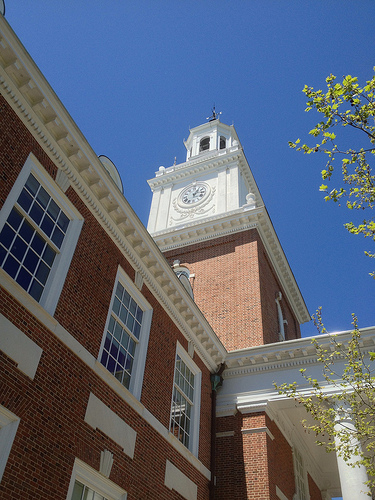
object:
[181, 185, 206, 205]
clock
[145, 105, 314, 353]
tower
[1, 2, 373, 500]
building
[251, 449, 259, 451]
brick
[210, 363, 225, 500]
rain gutter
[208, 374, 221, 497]
corner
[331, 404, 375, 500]
column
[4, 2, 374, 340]
sky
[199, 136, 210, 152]
opening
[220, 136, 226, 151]
opening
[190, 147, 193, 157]
opening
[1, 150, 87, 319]
window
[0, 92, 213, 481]
upper floor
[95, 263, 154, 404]
window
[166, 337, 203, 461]
window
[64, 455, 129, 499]
window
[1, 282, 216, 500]
ground floor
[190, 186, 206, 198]
2:15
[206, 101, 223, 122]
vane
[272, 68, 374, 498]
tree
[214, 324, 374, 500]
porch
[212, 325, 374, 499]
awning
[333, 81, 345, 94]
leaves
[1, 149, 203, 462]
three windows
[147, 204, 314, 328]
trim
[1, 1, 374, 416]
trim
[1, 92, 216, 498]
wall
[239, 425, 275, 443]
decoration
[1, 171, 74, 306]
20 panes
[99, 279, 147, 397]
20 panes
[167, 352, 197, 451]
20 panes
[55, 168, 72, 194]
white decoration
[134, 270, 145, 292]
decoration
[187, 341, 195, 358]
decoration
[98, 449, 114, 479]
decoration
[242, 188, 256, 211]
decoration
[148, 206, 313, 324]
eave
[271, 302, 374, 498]
foliage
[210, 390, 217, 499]
pipe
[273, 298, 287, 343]
window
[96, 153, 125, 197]
window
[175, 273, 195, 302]
window